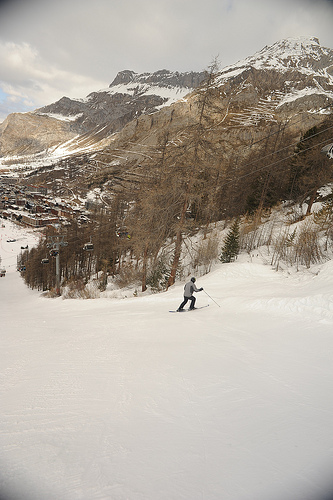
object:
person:
[175, 274, 204, 314]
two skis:
[169, 302, 213, 318]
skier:
[167, 272, 222, 314]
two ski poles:
[201, 286, 224, 311]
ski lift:
[115, 222, 130, 244]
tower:
[53, 254, 63, 296]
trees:
[14, 51, 332, 302]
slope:
[2, 291, 332, 499]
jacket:
[183, 283, 201, 298]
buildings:
[0, 188, 72, 228]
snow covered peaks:
[245, 35, 333, 72]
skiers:
[50, 248, 61, 266]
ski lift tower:
[40, 238, 64, 296]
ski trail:
[0, 277, 333, 499]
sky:
[0, 0, 333, 119]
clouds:
[0, 38, 109, 110]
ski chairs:
[114, 216, 134, 245]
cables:
[216, 142, 331, 192]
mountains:
[137, 33, 331, 201]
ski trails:
[50, 135, 96, 159]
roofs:
[13, 207, 25, 216]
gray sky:
[0, 1, 333, 102]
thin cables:
[231, 127, 331, 173]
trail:
[0, 299, 332, 499]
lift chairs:
[81, 235, 97, 256]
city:
[1, 180, 64, 230]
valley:
[0, 37, 332, 290]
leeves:
[141, 173, 162, 218]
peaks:
[229, 33, 331, 89]